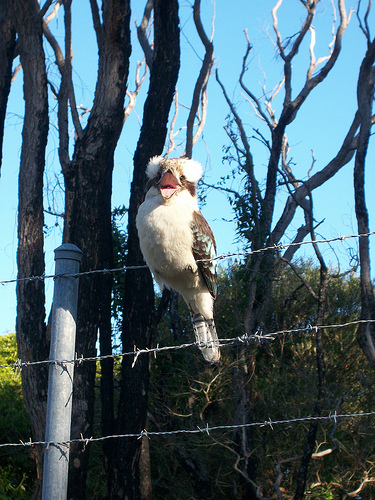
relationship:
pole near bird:
[37, 242, 85, 499] [136, 155, 224, 367]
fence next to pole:
[0, 228, 375, 448] [37, 242, 85, 499]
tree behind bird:
[1, 0, 133, 499] [136, 155, 224, 367]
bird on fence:
[136, 155, 224, 367] [0, 228, 375, 448]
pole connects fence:
[37, 242, 85, 499] [0, 228, 375, 448]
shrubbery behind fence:
[0, 259, 375, 499] [0, 228, 375, 448]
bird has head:
[136, 155, 224, 367] [143, 154, 205, 204]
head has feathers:
[143, 154, 205, 204] [178, 159, 205, 186]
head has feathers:
[143, 154, 205, 204] [143, 154, 165, 183]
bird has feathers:
[136, 155, 224, 367] [190, 210, 219, 302]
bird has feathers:
[136, 155, 224, 367] [190, 303, 222, 367]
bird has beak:
[136, 155, 224, 367] [154, 167, 183, 201]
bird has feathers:
[136, 155, 224, 367] [178, 159, 205, 186]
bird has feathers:
[136, 155, 224, 367] [143, 154, 165, 183]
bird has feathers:
[136, 155, 224, 367] [133, 187, 197, 286]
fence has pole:
[0, 228, 375, 448] [37, 242, 85, 499]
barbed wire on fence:
[1, 319, 374, 373] [0, 228, 375, 448]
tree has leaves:
[203, 67, 262, 269] [223, 190, 259, 243]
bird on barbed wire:
[136, 155, 224, 367] [1, 228, 374, 284]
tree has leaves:
[1, 331, 54, 499] [1, 334, 35, 498]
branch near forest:
[238, 23, 278, 133] [1, 2, 371, 499]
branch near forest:
[305, 146, 318, 182] [1, 2, 371, 499]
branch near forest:
[288, 0, 349, 116] [1, 2, 371, 499]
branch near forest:
[353, 1, 372, 50] [1, 2, 371, 499]